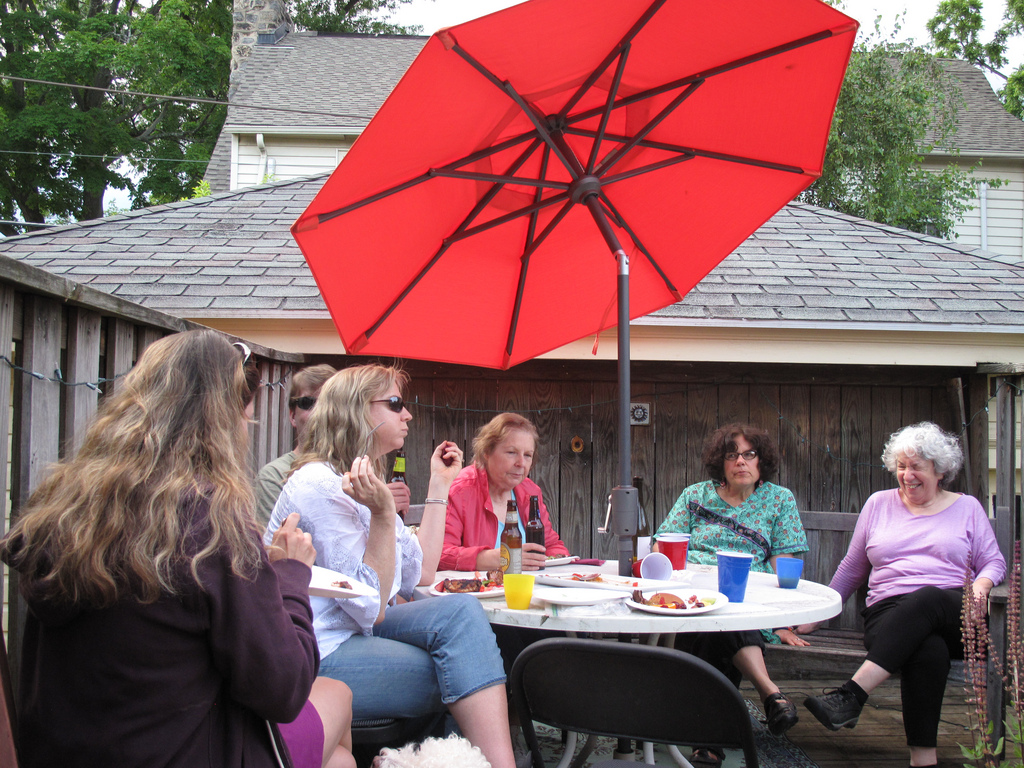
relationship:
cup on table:
[705, 546, 776, 619] [369, 544, 866, 656]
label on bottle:
[381, 455, 420, 487] [366, 437, 421, 533]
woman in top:
[647, 417, 813, 741] [647, 468, 813, 580]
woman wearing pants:
[647, 417, 813, 741] [647, 614, 813, 700]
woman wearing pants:
[274, 370, 508, 766] [314, 592, 511, 713]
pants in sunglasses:
[274, 575, 508, 737] [274, 370, 508, 440]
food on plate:
[620, 582, 732, 624] [620, 582, 732, 624]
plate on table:
[620, 582, 732, 624] [369, 544, 866, 656]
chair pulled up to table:
[515, 633, 757, 766] [391, 537, 864, 652]